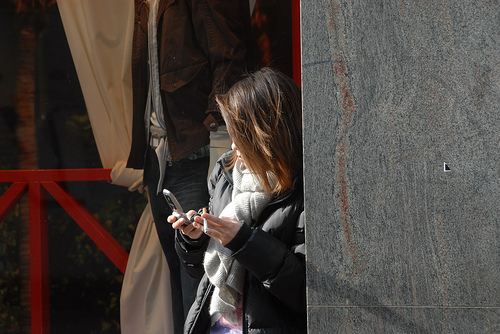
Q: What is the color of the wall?
A: Grey.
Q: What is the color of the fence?
A: Red.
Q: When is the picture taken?
A: Daytime.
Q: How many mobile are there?
A: One.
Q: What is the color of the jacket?
A: Black.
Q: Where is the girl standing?
A: Near the wall.